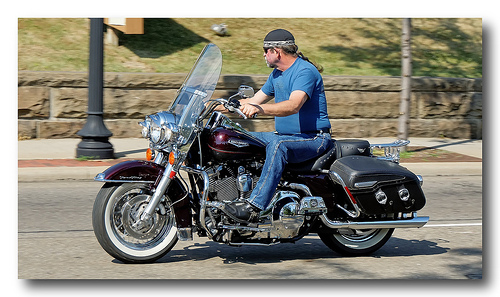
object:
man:
[223, 26, 329, 218]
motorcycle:
[93, 44, 422, 259]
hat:
[260, 29, 304, 48]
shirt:
[259, 59, 344, 137]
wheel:
[90, 170, 186, 264]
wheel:
[318, 190, 397, 256]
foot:
[224, 192, 263, 220]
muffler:
[320, 200, 440, 234]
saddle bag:
[323, 154, 426, 214]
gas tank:
[206, 125, 262, 155]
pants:
[249, 129, 332, 204]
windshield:
[164, 44, 224, 137]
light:
[150, 112, 166, 144]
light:
[167, 127, 180, 142]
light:
[137, 114, 153, 132]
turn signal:
[165, 152, 187, 171]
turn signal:
[139, 142, 158, 160]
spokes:
[118, 199, 164, 237]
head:
[258, 29, 299, 71]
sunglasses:
[263, 46, 276, 57]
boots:
[225, 197, 261, 217]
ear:
[275, 46, 284, 60]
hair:
[275, 44, 326, 73]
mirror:
[236, 80, 258, 104]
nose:
[262, 51, 273, 60]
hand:
[239, 107, 265, 122]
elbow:
[281, 91, 306, 120]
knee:
[264, 135, 303, 169]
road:
[32, 173, 475, 277]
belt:
[301, 127, 337, 136]